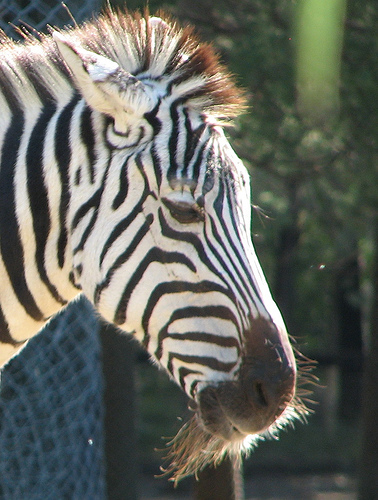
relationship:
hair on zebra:
[144, 379, 315, 485] [0, 1, 328, 487]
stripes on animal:
[0, 117, 112, 246] [3, 73, 350, 448]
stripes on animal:
[6, 88, 255, 381] [1, 4, 322, 485]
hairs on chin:
[152, 330, 328, 488] [182, 377, 250, 446]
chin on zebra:
[182, 377, 250, 446] [0, 1, 328, 487]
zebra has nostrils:
[0, 1, 328, 487] [242, 362, 280, 414]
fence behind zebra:
[9, 300, 109, 497] [0, 1, 328, 487]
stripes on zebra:
[20, 109, 101, 157] [7, 12, 352, 445]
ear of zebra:
[62, 43, 141, 112] [0, 1, 328, 487]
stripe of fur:
[45, 104, 79, 263] [0, 8, 320, 485]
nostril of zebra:
[249, 376, 272, 410] [0, 1, 328, 487]